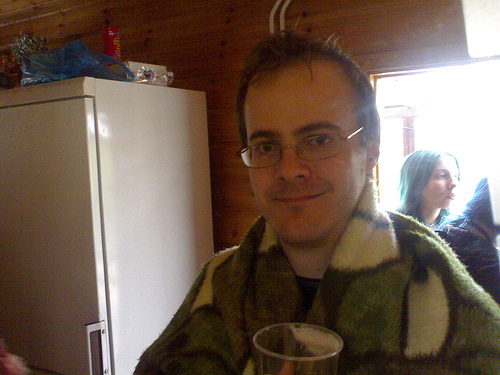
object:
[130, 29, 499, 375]
man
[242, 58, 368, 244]
face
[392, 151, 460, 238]
woman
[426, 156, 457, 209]
face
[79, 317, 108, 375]
handle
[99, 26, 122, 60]
goods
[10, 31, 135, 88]
bag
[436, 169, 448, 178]
right eye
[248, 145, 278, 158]
right eye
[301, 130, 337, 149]
left eye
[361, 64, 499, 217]
light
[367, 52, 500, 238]
window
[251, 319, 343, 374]
mug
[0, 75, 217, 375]
refrigerator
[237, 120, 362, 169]
glasses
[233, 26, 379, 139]
hair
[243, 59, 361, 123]
forehead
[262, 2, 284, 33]
cord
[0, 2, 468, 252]
wall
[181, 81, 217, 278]
shadow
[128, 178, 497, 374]
blanket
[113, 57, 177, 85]
item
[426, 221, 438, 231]
necklace